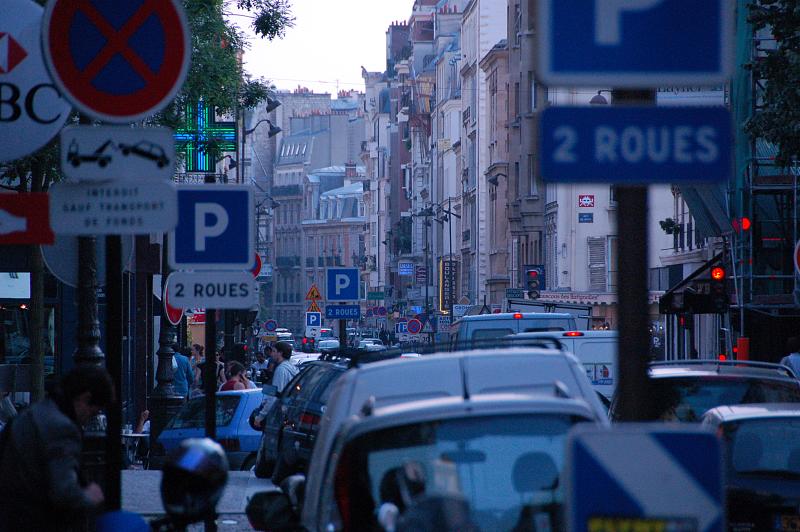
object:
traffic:
[0, 313, 800, 529]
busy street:
[0, 351, 800, 532]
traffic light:
[709, 217, 752, 281]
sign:
[0, 0, 73, 162]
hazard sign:
[305, 282, 322, 312]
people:
[155, 342, 301, 396]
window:
[278, 310, 285, 327]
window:
[587, 236, 605, 263]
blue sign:
[535, 0, 737, 185]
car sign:
[38, 0, 191, 235]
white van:
[304, 346, 610, 532]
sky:
[219, 0, 413, 100]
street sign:
[166, 185, 257, 309]